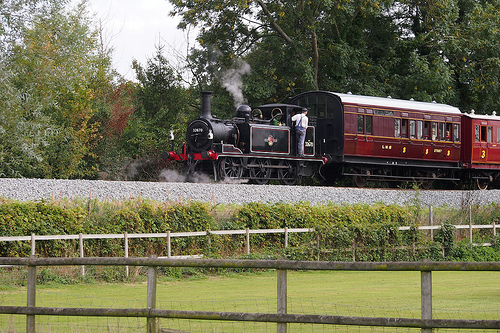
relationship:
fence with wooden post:
[0, 223, 500, 333] [418, 258, 435, 331]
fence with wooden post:
[0, 223, 500, 333] [272, 260, 290, 332]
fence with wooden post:
[0, 223, 500, 333] [144, 258, 158, 329]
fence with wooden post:
[0, 223, 500, 333] [24, 256, 38, 331]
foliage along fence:
[4, 195, 499, 261] [3, 233, 494, 327]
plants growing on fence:
[305, 205, 455, 260] [0, 204, 498, 277]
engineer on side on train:
[291, 108, 308, 158] [161, 82, 498, 185]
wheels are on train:
[221, 153, 300, 185] [119, 29, 499, 260]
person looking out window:
[442, 124, 449, 144] [441, 117, 457, 143]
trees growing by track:
[65, 81, 152, 180] [58, 169, 233, 190]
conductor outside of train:
[291, 108, 309, 158] [165, 72, 497, 192]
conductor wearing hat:
[290, 107, 310, 157] [302, 103, 317, 116]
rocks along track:
[2, 183, 491, 212] [0, 173, 500, 191]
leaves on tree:
[112, 108, 129, 130] [87, 60, 143, 164]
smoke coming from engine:
[208, 47, 254, 107] [181, 86, 327, 181]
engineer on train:
[287, 105, 313, 156] [173, 91, 498, 184]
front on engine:
[174, 72, 394, 186] [162, 91, 323, 186]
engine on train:
[182, 92, 322, 180] [173, 91, 498, 184]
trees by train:
[0, 25, 492, 189] [165, 72, 497, 192]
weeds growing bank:
[3, 193, 493, 264] [117, 174, 348, 242]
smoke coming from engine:
[216, 59, 247, 109] [172, 78, 332, 176]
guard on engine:
[162, 148, 216, 168] [163, 80, 323, 182]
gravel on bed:
[1, 178, 500, 206] [4, 172, 484, 207]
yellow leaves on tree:
[29, 27, 108, 147] [6, 2, 103, 172]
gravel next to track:
[1, 175, 498, 205] [3, 173, 484, 193]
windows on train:
[356, 111, 373, 136] [165, 72, 497, 192]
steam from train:
[222, 54, 250, 110] [161, 82, 498, 185]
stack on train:
[200, 89, 215, 118] [161, 70, 481, 188]